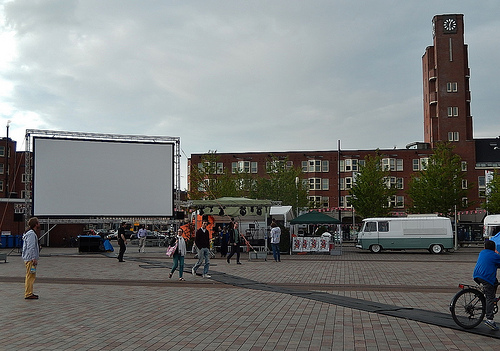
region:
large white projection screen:
[25, 127, 186, 224]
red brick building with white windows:
[186, 142, 473, 211]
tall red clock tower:
[419, 8, 486, 208]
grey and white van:
[353, 213, 455, 252]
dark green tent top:
[290, 205, 344, 257]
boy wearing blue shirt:
[434, 229, 499, 341]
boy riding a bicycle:
[452, 237, 497, 342]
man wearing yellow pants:
[22, 215, 49, 305]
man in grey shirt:
[20, 215, 46, 297]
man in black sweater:
[192, 217, 216, 285]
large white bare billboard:
[30, 123, 182, 237]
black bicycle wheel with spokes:
[437, 287, 495, 333]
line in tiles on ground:
[133, 284, 341, 341]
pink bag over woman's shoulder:
[161, 239, 181, 259]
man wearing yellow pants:
[20, 257, 49, 290]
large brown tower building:
[408, 57, 486, 137]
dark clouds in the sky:
[41, 72, 262, 117]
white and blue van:
[349, 209, 456, 255]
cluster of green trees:
[200, 159, 453, 201]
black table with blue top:
[74, 227, 118, 267]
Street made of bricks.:
[132, 298, 369, 348]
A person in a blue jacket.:
[468, 236, 498, 292]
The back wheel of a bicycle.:
[444, 247, 496, 337]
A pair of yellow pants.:
[16, 245, 51, 307]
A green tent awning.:
[291, 204, 345, 234]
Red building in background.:
[193, 130, 428, 205]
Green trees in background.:
[194, 152, 455, 208]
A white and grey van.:
[351, 202, 457, 258]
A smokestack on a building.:
[3, 118, 18, 157]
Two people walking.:
[162, 218, 229, 290]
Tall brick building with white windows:
[406, 1, 487, 226]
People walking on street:
[49, 210, 288, 310]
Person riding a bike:
[447, 230, 497, 336]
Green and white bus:
[346, 213, 456, 263]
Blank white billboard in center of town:
[5, 127, 181, 230]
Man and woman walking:
[160, 213, 215, 285]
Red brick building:
[187, 6, 494, 236]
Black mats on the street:
[250, 267, 415, 323]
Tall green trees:
[323, 146, 463, 257]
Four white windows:
[300, 156, 331, 174]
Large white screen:
[30, 135, 176, 217]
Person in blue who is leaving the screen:
[471, 236, 497, 326]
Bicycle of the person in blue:
[448, 278, 498, 332]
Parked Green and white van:
[353, 212, 457, 257]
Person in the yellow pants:
[18, 211, 48, 304]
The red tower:
[417, 11, 476, 210]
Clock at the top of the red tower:
[439, 10, 459, 35]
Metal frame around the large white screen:
[21, 125, 183, 230]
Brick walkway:
[1, 248, 496, 350]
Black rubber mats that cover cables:
[113, 245, 498, 347]